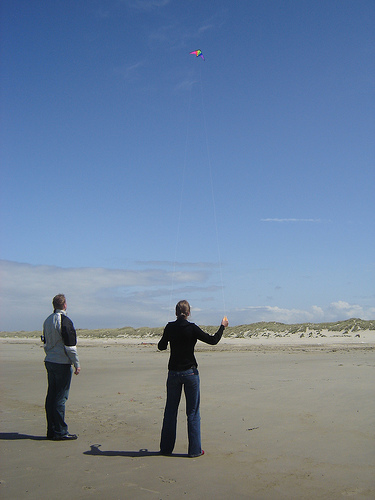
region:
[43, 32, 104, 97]
this is the sky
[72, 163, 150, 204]
the sky is blue in color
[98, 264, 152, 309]
the sky has clouds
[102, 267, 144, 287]
the clouds are white in color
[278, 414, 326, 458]
this is the ground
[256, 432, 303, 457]
the ground has sand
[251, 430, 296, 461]
the sand is brown in color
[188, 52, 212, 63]
this is a kite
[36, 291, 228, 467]
these are two people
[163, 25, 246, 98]
the kite is in the sky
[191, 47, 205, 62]
colored kite in sky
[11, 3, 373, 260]
blue of daytime sky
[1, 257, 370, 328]
clouds low in sky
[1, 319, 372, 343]
grass on sandy hill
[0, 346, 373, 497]
flat sand on ground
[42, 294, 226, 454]
two people looking up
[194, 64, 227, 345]
hand holding kite string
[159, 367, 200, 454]
back of blue jeans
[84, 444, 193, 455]
shadow on smooth sand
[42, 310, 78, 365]
two toned jacket on man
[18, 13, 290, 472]
lady flying a kite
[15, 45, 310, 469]
lady flying kite on wet sand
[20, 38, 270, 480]
lady flying kite on beach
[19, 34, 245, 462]
man watching lady fly kite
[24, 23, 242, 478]
man watching lady fly kite on wet sand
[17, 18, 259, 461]
man watching lady fly kite on beach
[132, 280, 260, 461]
woman wearing black shirt and blue jeans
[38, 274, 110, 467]
man wearing coat and jeans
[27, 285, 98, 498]
man wearing grey, white, and black coat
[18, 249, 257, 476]
man and woman on beach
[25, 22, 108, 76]
this is the sky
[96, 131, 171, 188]
the sky is blue in color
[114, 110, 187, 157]
the sky has clouds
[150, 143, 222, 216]
the clouds are white in color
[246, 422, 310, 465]
this is the ground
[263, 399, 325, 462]
the ground has sand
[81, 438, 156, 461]
this is a shadow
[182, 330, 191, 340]
the sweater is black in color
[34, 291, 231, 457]
Two people standing on a beach.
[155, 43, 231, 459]
Woman flying a kite.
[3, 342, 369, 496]
A sandy beach.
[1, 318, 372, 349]
Sand dunes in the distance.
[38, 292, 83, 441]
Man looking up into the sky.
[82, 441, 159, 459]
Woman's shadow on the ground.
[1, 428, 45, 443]
Man's shadow in the sand.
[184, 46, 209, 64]
Kite in the sky.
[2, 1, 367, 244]
Clear blue sky with a kite.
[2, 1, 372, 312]
Blue sky with white clouds.